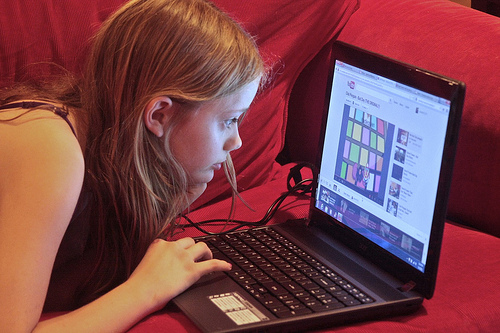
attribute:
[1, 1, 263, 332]
girl — little, young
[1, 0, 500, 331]
couch — red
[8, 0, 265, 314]
hair — long, brown, blonde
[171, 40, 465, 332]
laptop — black, bright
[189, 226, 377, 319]
keyboard — black